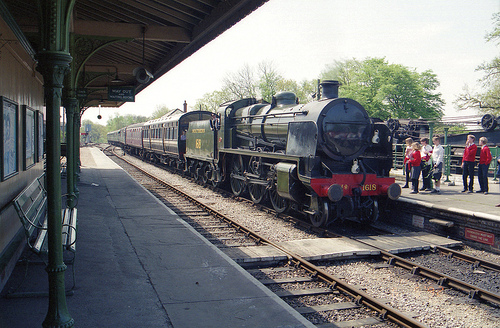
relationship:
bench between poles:
[14, 176, 79, 297] [32, 1, 82, 328]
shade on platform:
[0, 170, 340, 327] [1, 146, 318, 327]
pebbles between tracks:
[329, 263, 420, 297] [100, 142, 500, 325]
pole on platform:
[61, 101, 78, 209] [1, 146, 318, 327]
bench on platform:
[14, 176, 79, 297] [1, 146, 318, 327]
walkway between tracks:
[219, 233, 464, 268] [100, 142, 500, 325]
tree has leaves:
[309, 59, 449, 124] [370, 65, 392, 88]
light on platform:
[133, 63, 156, 85] [1, 146, 318, 327]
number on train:
[360, 184, 381, 192] [107, 80, 403, 229]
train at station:
[107, 80, 403, 229] [0, 143, 500, 327]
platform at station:
[1, 146, 318, 327] [0, 143, 500, 327]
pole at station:
[61, 101, 78, 209] [0, 143, 500, 327]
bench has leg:
[14, 176, 79, 297] [66, 264, 84, 297]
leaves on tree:
[370, 65, 392, 88] [309, 59, 449, 124]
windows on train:
[140, 124, 180, 140] [107, 80, 403, 229]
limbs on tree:
[455, 93, 499, 114] [456, 10, 500, 118]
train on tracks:
[107, 80, 403, 229] [100, 142, 500, 325]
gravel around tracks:
[248, 210, 275, 232] [100, 142, 500, 325]